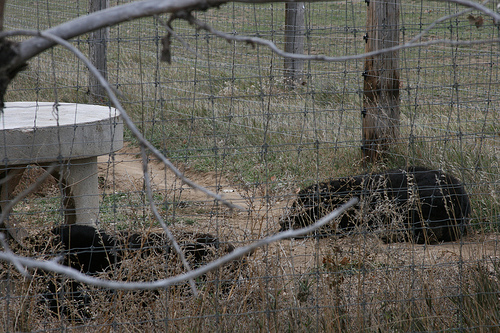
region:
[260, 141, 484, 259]
The dog is lying down.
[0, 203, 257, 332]
The dog is lying down.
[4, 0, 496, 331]
The fence is metal wire.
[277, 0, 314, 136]
The fence post is wood.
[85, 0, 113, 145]
The fence post is wood.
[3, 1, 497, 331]
The grass is turning brown.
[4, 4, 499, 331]
The grass is overgrown.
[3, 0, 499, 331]
The grass is dry.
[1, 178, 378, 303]
The tree limb is bare.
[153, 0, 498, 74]
The tree limb is bare.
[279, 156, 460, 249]
large bear laying down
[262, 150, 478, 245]
large bear in enclosure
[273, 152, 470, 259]
large black bear laying down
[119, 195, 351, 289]
small tree branch in middle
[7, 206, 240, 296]
large bear laying down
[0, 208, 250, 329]
large black bear laying down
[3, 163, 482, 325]
two bears laying down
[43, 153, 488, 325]
two bears near each other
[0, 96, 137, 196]
concrete structure on ground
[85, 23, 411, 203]
metal chicken wire fence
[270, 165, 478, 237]
a bear in a cage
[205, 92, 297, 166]
a silver part of a fence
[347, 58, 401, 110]
a large brown post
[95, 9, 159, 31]
a small brown branch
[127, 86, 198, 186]
a twig without leaves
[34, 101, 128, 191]
a large cement bench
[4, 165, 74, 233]
the empty space under a bench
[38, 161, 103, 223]
the leg of a bench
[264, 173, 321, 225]
the head of a bear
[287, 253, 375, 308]
a bunch of dead grass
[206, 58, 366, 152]
wired fencing holding in animals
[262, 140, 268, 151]
crossover of fencing wire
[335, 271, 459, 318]
brown and golden grass growing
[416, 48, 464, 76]
patches of green grass growing in background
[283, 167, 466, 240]
dark furred animal laying down on ground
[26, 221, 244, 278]
dark furred animal laying near concrete item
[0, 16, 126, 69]
branches and twigs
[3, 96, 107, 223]
concrete table-like structure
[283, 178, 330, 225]
head of the animal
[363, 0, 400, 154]
wooden post for holding fence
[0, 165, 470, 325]
two black bears laying on the ground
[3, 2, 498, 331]
a silver wire fence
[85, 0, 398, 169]
three wooden posts holding a wire fence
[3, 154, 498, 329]
brown dead grass and weeds along the fence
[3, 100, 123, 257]
a gray concrete dish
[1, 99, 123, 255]
a gray water bowl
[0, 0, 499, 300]
gray tree branches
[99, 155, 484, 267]
tan bare ground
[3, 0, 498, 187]
gray and tan colored dry grass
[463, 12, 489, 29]
a dried brown leaf